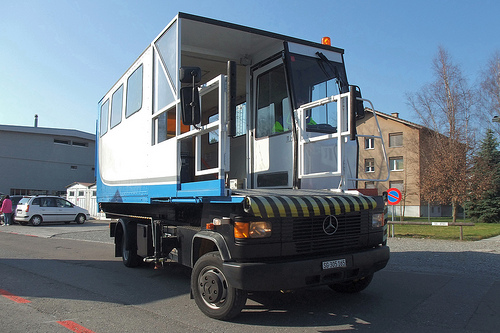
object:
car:
[12, 194, 91, 225]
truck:
[93, 10, 392, 326]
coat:
[1, 199, 12, 214]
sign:
[386, 185, 401, 235]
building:
[348, 95, 477, 231]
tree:
[402, 40, 490, 240]